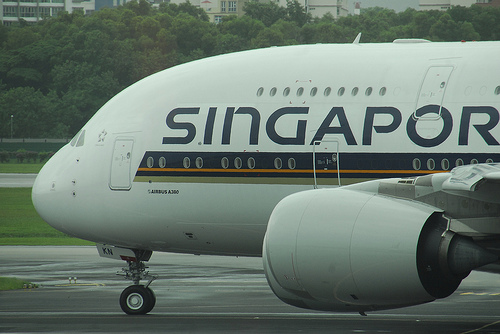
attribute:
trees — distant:
[6, 3, 499, 45]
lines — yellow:
[130, 163, 446, 183]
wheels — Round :
[117, 280, 155, 317]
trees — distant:
[4, 16, 102, 112]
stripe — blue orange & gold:
[132, 150, 499, 186]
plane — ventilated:
[31, 26, 499, 316]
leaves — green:
[52, 60, 97, 84]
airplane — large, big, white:
[29, 28, 499, 313]